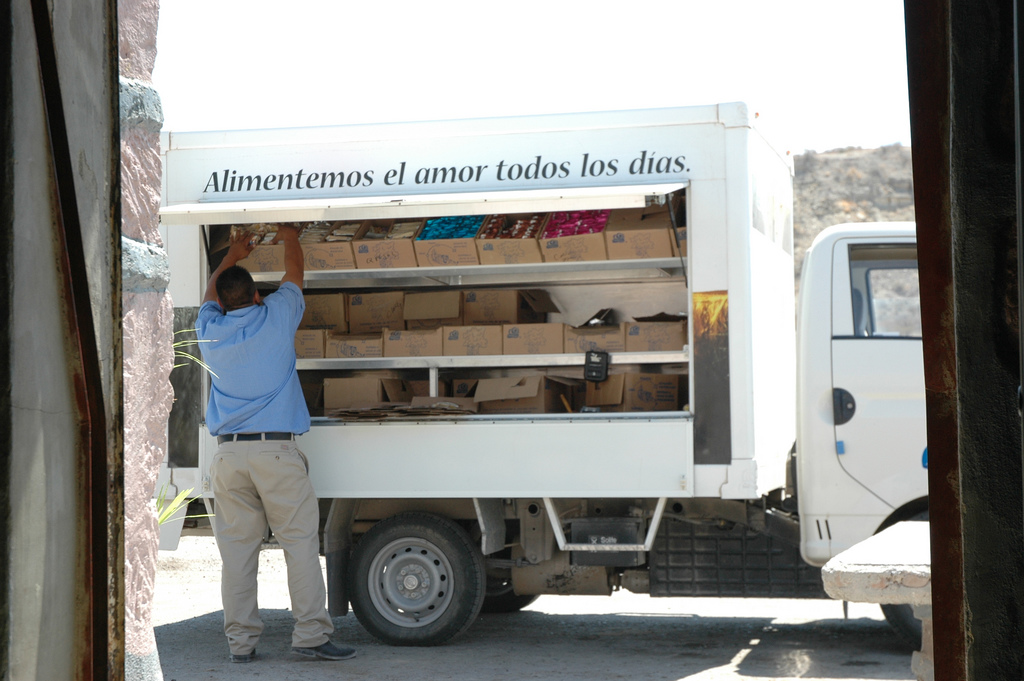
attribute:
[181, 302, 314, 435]
shirt — blue 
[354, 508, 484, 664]
tire — black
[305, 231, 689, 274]
boxes — supplies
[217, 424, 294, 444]
belt — brown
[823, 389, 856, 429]
handle — black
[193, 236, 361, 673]
hair — short cropped, black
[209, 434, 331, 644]
pants — tan, dress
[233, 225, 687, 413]
boxes — carboard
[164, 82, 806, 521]
body — truck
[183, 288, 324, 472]
shirt — blue